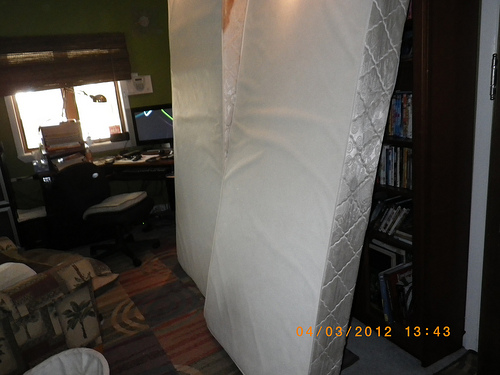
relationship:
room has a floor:
[1, 1, 500, 374] [64, 207, 500, 372]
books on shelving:
[365, 1, 414, 321] [350, 1, 480, 369]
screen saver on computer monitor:
[135, 108, 175, 142] [130, 102, 177, 152]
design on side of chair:
[63, 299, 93, 343] [0, 235, 101, 375]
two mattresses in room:
[165, 0, 413, 375] [1, 1, 500, 374]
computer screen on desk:
[130, 102, 177, 152] [91, 155, 174, 180]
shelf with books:
[350, 1, 480, 369] [365, 1, 414, 321]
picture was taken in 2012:
[0, 0, 499, 374] [353, 324, 393, 340]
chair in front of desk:
[56, 160, 163, 268] [91, 155, 174, 180]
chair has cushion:
[56, 160, 163, 268] [82, 186, 149, 219]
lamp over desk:
[109, 132, 132, 159] [91, 155, 174, 180]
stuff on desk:
[87, 144, 178, 166] [91, 155, 174, 180]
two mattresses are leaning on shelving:
[165, 0, 413, 375] [350, 1, 480, 369]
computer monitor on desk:
[130, 102, 177, 152] [91, 155, 174, 180]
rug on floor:
[80, 236, 358, 374] [64, 207, 500, 372]